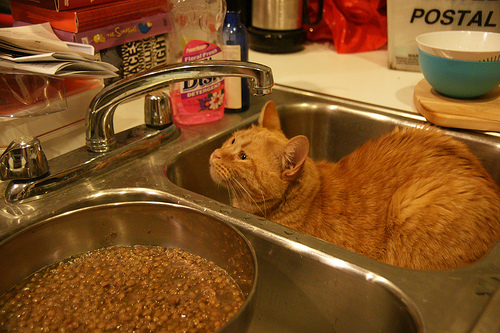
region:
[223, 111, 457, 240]
A brown cat inside a kitchen sink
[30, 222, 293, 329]
Brown lentil beans in a silver plate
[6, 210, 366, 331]
Brown lentil beans in a silver sink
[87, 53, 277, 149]
Kitchen silver dripping tap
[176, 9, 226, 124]
Dish washing liquid soap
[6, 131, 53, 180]
A silver Water tap opener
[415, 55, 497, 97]
A blue plastic bowl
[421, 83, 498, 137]
A wooden chopping board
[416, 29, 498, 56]
A white melamine plate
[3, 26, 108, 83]
Waste paper on the sink table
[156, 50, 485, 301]
A cat in a sink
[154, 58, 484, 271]
An orange cat in a sink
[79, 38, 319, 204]
The faucet on a sink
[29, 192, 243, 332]
Beans in a bowl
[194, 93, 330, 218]
The head of a cat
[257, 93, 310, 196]
The ears of a cat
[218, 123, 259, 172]
The eyes of a cat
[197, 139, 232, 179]
The nose of a cat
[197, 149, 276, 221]
The whiskers of a cat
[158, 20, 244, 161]
pink dish soap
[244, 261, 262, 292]
edge of a bowl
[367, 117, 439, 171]
edge of a pussy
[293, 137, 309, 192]
edge of an ear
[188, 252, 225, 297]
part of some beans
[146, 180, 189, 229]
part of a trough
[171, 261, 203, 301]
part of a water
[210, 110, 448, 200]
this is a cat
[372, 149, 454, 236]
the fur is brown in color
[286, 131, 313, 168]
this is the ear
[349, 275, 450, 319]
this is a sink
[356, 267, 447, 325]
the sink is metallic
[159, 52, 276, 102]
this is a tap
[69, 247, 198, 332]
beans are in a container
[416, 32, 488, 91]
this is a plate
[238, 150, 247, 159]
this is the eye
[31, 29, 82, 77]
this is a newspaper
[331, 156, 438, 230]
body of cat in sink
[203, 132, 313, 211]
head of cat in sink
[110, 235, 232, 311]
large bowl of beans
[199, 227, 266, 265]
large stainless steel bowl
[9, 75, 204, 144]
stainless steel sink faucet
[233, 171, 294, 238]
cat has long whiskers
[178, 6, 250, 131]
bottle of dish detergent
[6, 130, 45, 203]
knob on stainless faucet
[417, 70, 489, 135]
wooden cutting board near sink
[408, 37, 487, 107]
bowl on cutting board